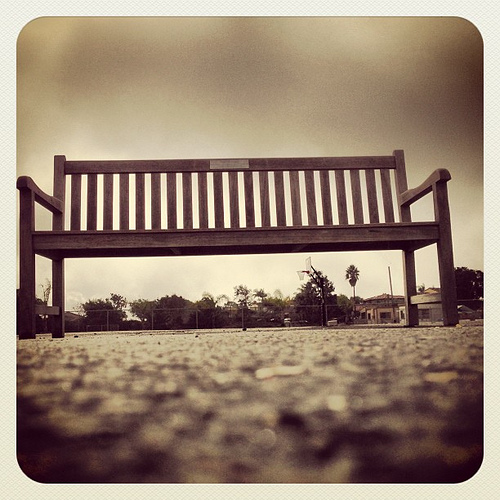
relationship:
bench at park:
[17, 155, 460, 339] [18, 17, 482, 485]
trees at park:
[32, 265, 483, 333] [18, 17, 482, 485]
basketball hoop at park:
[298, 268, 310, 282] [18, 17, 482, 485]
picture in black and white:
[0, 0, 499, 499] [1, 0, 498, 497]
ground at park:
[17, 320, 483, 485] [18, 17, 482, 485]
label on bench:
[209, 159, 250, 170] [17, 155, 460, 339]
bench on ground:
[17, 155, 460, 339] [17, 320, 483, 485]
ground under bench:
[17, 320, 483, 485] [17, 155, 460, 339]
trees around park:
[32, 265, 483, 333] [18, 17, 482, 485]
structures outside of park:
[353, 289, 482, 321] [18, 17, 482, 485]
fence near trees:
[68, 302, 366, 327] [32, 265, 483, 333]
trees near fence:
[32, 265, 483, 333] [68, 302, 366, 327]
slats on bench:
[63, 156, 402, 232] [17, 155, 460, 339]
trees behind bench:
[32, 265, 483, 333] [17, 155, 460, 339]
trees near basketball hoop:
[32, 265, 483, 333] [298, 268, 310, 282]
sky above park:
[17, 17, 483, 320] [18, 17, 482, 485]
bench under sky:
[17, 155, 460, 339] [17, 17, 483, 320]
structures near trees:
[353, 289, 482, 321] [32, 265, 483, 333]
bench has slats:
[17, 155, 460, 339] [63, 156, 402, 232]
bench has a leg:
[17, 155, 460, 339] [434, 242, 458, 325]